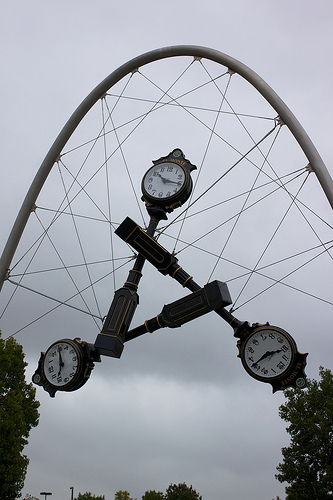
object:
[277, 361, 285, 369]
numbers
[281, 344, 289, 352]
numbers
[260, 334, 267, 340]
numbers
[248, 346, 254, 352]
numbers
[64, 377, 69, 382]
numbers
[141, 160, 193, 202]
clock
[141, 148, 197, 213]
clock face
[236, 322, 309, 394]
clock face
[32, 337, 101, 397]
clock face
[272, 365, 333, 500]
tree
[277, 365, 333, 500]
leaves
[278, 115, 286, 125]
wall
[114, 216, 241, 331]
pole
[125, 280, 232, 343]
pole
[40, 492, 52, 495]
light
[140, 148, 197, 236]
knee pads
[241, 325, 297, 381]
clock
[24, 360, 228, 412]
light sky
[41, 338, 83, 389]
clock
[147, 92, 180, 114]
wall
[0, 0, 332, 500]
sky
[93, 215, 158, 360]
pole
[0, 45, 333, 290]
bar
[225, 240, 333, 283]
cables.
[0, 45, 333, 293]
arch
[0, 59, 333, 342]
web